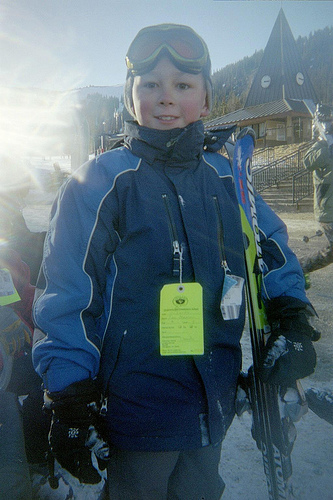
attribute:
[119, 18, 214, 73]
goggles — green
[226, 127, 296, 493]
skis — blue, green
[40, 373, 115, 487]
gloves — black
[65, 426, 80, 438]
logo — white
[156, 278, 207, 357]
tag — neon, yellow